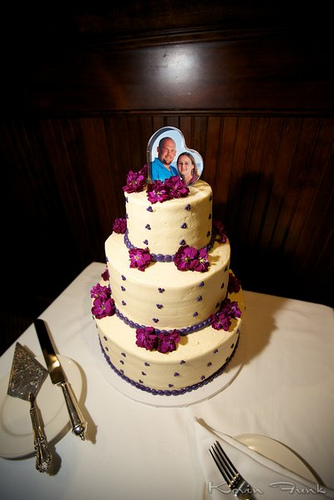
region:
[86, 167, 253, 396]
Three tier wedding cake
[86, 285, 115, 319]
Purple flowers on cake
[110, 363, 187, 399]
Purple trim on wedding cake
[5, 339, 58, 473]
Silver cake server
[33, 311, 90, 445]
A silver cake knife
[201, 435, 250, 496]
A silver fork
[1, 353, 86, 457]
White ceramic plate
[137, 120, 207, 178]
Glass heart on top of wedding cake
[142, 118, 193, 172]
Photo inside of glass heart on top of cake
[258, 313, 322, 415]
White table cloth under wedding cake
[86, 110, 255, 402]
an anniversary cake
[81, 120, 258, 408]
cake has three layers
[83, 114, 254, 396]
picture of a couple on top a cake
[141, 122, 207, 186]
picture shaped like a heart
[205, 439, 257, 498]
a silver fork on a table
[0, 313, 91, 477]
a knife and a spatula over a dish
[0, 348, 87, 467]
white dish over a table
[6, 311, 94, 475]
spatula and knife is color silver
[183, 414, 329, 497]
a white napkin over a dish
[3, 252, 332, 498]
table is covered with white tablecloth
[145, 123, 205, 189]
picture of couple getting married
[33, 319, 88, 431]
silver cake cutting knife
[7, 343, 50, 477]
silver decorative cake server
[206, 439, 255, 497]
silver fork on dinner napkin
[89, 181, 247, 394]
three tier wedding cake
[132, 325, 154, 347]
purple flower cake decoration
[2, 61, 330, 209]
brown wood paneled wall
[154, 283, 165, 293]
blue wedding cake decoration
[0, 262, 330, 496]
white tablecloth on table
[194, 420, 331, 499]
folded white dinner napkin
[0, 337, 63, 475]
silver metal eating utensil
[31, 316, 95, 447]
silver metal eating utensil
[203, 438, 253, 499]
silver metal eating utensil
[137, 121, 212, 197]
picture in silver frame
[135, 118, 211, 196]
picture in heart shaped frame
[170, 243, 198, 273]
decorative purple flower on a cake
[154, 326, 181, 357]
decorative purple flower on a cake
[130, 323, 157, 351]
decorative purple flower on a cake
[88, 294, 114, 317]
decorative purple flower on a cake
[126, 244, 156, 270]
decorative purple flower on a cake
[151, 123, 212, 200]
couple's picture on a heart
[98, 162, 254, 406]
purple and white wedding cake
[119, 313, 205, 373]
purple flowers on the cake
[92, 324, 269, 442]
cake sitting on round circular plate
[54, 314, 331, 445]
cake sitting on table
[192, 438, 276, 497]
a fork on a napkin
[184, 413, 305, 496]
fork and napkin on a plate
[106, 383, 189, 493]
table is white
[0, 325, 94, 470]
cake server and a knife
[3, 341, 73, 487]
cake server is ornate